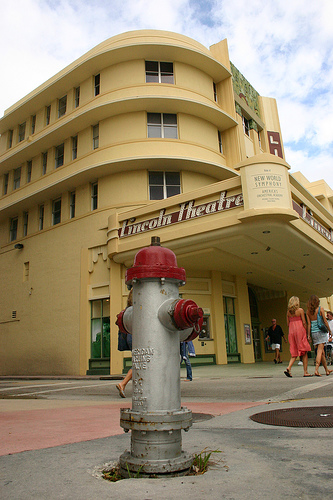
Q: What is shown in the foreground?
A: Fire hydrant.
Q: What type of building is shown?
A: Theatre.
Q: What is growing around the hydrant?
A: Grass.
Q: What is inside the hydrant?
A: Water.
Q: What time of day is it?
A: Daytime.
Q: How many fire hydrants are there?
A: One.